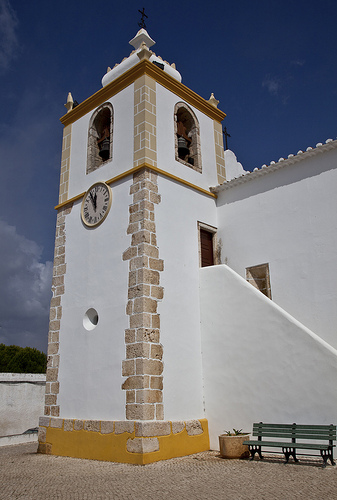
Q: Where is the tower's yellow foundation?
A: Bottom of the tower.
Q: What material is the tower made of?
A: Brick and stucco.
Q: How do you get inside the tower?
A: Stairs.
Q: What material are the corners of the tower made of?
A: Brick.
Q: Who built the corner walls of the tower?
A: Bricklayers.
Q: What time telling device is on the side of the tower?
A: Clock.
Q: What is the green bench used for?
A: Sitting.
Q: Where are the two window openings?
A: Top of the building.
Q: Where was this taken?
A: In a plaza.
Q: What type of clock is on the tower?
A: An analog clock.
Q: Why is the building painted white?
A: To reflect sunlight.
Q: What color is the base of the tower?
A: Yellow.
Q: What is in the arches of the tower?
A: Bells.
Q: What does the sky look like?
A: It is cloudy.